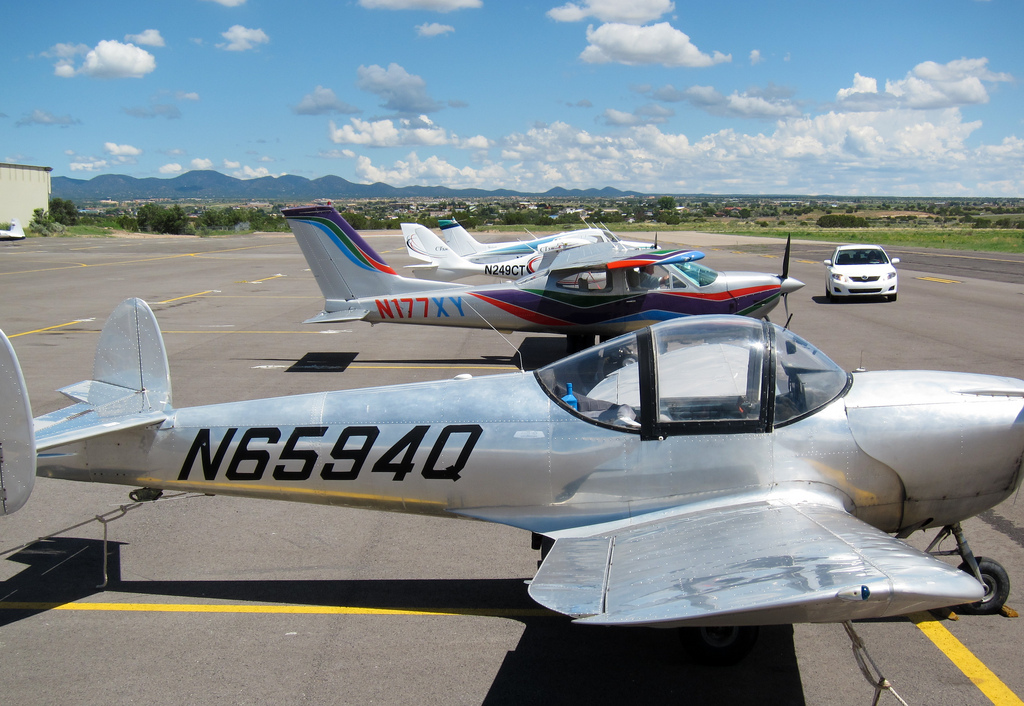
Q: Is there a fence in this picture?
A: No, there are no fences.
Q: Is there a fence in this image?
A: No, there are no fences.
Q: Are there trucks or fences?
A: No, there are no fences or trucks.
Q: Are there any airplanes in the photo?
A: Yes, there is an airplane.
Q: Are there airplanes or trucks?
A: Yes, there is an airplane.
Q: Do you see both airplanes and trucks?
A: No, there is an airplane but no trucks.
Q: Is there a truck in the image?
A: No, there are no trucks.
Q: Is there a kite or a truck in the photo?
A: No, there are no trucks or kites.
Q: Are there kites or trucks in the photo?
A: No, there are no trucks or kites.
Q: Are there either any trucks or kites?
A: No, there are no trucks or kites.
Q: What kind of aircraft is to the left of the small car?
A: The aircraft is an airplane.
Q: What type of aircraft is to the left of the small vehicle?
A: The aircraft is an airplane.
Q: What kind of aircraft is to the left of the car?
A: The aircraft is an airplane.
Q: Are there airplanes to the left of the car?
A: Yes, there is an airplane to the left of the car.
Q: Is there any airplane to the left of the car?
A: Yes, there is an airplane to the left of the car.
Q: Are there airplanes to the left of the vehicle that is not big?
A: Yes, there is an airplane to the left of the car.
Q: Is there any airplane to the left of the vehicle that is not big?
A: Yes, there is an airplane to the left of the car.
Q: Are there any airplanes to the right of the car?
A: No, the airplane is to the left of the car.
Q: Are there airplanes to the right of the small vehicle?
A: No, the airplane is to the left of the car.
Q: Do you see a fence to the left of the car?
A: No, there is an airplane to the left of the car.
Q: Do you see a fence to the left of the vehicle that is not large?
A: No, there is an airplane to the left of the car.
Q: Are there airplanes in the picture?
A: Yes, there is an airplane.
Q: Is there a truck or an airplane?
A: Yes, there is an airplane.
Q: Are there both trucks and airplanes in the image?
A: No, there is an airplane but no trucks.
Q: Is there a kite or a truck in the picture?
A: No, there are no kites or trucks.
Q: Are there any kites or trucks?
A: No, there are no kites or trucks.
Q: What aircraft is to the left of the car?
A: The aircraft is an airplane.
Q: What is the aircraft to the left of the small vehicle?
A: The aircraft is an airplane.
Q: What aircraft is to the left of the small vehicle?
A: The aircraft is an airplane.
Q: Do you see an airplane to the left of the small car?
A: Yes, there is an airplane to the left of the car.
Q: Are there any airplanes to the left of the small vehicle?
A: Yes, there is an airplane to the left of the car.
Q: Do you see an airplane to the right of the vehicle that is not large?
A: No, the airplane is to the left of the car.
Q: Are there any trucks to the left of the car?
A: No, there is an airplane to the left of the car.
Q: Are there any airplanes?
A: Yes, there is an airplane.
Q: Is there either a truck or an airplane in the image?
A: Yes, there is an airplane.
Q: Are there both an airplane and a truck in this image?
A: No, there is an airplane but no trucks.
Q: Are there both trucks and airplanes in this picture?
A: No, there is an airplane but no trucks.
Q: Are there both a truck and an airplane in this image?
A: No, there is an airplane but no trucks.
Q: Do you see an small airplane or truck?
A: Yes, there is a small airplane.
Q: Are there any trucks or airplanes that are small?
A: Yes, the airplane is small.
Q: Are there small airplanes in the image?
A: Yes, there is a small airplane.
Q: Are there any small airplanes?
A: Yes, there is a small airplane.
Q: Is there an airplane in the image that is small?
A: Yes, there is an airplane that is small.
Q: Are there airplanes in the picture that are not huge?
A: Yes, there is a small airplane.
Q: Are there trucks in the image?
A: No, there are no trucks.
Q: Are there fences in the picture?
A: No, there are no fences.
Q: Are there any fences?
A: No, there are no fences.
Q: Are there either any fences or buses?
A: No, there are no fences or buses.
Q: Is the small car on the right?
A: Yes, the car is on the right of the image.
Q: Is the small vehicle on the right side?
A: Yes, the car is on the right of the image.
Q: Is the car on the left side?
A: No, the car is on the right of the image.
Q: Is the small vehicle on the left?
A: No, the car is on the right of the image.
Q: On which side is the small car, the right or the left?
A: The car is on the right of the image.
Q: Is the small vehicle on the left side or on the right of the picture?
A: The car is on the right of the image.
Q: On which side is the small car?
A: The car is on the right of the image.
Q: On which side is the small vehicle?
A: The car is on the right of the image.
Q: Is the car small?
A: Yes, the car is small.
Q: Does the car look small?
A: Yes, the car is small.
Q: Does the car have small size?
A: Yes, the car is small.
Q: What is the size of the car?
A: The car is small.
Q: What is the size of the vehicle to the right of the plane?
A: The car is small.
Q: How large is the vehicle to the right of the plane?
A: The car is small.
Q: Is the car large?
A: No, the car is small.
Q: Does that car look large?
A: No, the car is small.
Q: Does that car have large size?
A: No, the car is small.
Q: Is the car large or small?
A: The car is small.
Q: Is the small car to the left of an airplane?
A: No, the car is to the right of an airplane.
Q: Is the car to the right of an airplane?
A: Yes, the car is to the right of an airplane.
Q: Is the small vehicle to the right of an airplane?
A: Yes, the car is to the right of an airplane.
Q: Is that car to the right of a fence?
A: No, the car is to the right of an airplane.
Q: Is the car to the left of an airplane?
A: No, the car is to the right of an airplane.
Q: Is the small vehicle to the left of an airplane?
A: No, the car is to the right of an airplane.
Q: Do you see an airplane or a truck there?
A: Yes, there is an airplane.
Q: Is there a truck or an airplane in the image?
A: Yes, there is an airplane.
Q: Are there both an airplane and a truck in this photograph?
A: No, there is an airplane but no trucks.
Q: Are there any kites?
A: No, there are no kites.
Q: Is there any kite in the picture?
A: No, there are no kites.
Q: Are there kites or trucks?
A: No, there are no kites or trucks.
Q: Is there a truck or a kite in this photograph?
A: No, there are no kites or trucks.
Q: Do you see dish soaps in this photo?
A: No, there are no dish soaps.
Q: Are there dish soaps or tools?
A: No, there are no dish soaps or tools.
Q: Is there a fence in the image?
A: No, there are no fences.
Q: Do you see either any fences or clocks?
A: No, there are no fences or clocks.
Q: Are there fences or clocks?
A: No, there are no fences or clocks.